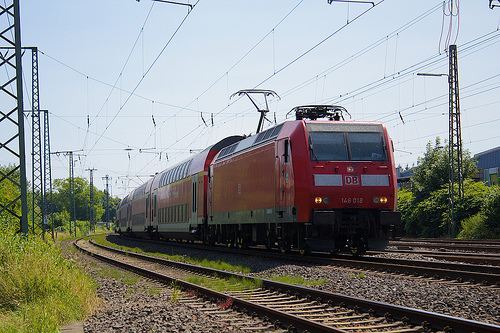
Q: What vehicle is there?
A: Train.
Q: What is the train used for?
A: Transporting.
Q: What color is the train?
A: Red.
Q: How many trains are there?
A: One.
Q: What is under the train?
A: Tracks.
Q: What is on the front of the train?
A: Lights.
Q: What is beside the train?
A: Trees.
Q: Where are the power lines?
A: Over train.